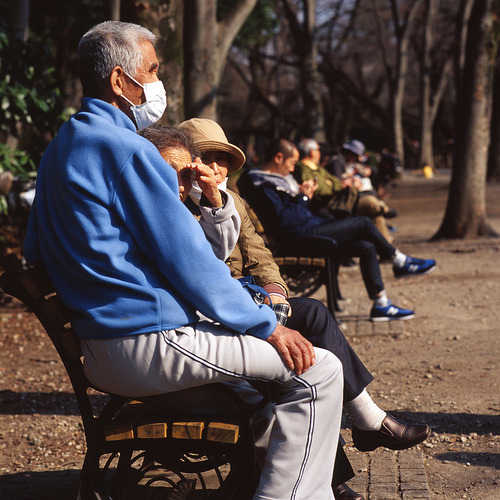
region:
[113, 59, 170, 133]
white disposable surgical mask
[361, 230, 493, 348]
blue shoes are visible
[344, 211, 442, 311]
blue shoes are visible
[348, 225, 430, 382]
blue shoes are visible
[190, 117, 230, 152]
woman wearing tan hat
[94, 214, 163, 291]
man wearing blue sweatshirt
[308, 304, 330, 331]
woman wearing blue pants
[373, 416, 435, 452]
woman wearing brown shoes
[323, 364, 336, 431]
man wearing white sweatpants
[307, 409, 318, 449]
black stripes on pants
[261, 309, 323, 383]
mans hand on thigh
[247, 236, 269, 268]
woman wears brown jacket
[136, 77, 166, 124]
mask on mans face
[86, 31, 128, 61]
mans hair is grey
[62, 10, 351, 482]
Man wears a face mask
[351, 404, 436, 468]
A brown slip on shoe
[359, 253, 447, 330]
Blue tennis shoes with white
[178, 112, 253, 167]
A tan hat on woman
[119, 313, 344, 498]
A white stripe on gray pants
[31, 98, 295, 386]
A light blue shirt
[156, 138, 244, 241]
Woman with hand to her face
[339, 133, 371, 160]
A grey hat in the distance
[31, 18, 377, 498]
Man sitting on a bench with two women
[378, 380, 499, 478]
A shadow cast on the ground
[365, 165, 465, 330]
blue shoes are visible